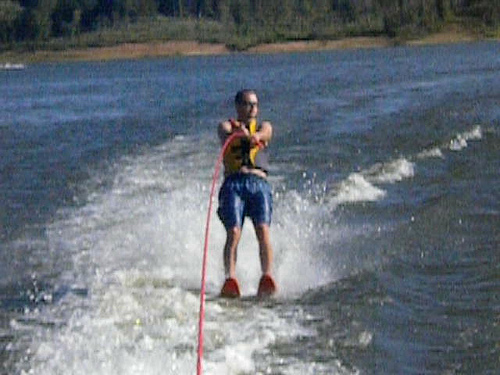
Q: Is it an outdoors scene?
A: Yes, it is outdoors.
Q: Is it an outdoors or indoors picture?
A: It is outdoors.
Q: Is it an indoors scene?
A: No, it is outdoors.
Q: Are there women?
A: No, there are no women.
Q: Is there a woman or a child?
A: No, there are no women or children.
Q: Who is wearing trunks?
A: The man is wearing trunks.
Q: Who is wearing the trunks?
A: The man is wearing trunks.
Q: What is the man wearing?
A: The man is wearing trunks.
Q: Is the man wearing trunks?
A: Yes, the man is wearing trunks.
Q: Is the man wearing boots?
A: No, the man is wearing trunks.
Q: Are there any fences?
A: No, there are no fences.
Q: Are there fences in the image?
A: No, there are no fences.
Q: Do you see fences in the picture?
A: No, there are no fences.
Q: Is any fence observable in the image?
A: No, there are no fences.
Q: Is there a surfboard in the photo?
A: No, there are no surfboards.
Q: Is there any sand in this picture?
A: Yes, there is sand.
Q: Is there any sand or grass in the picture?
A: Yes, there is sand.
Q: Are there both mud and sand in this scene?
A: No, there is sand but no mud.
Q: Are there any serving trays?
A: No, there are no serving trays.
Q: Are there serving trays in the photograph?
A: No, there are no serving trays.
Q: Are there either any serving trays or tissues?
A: No, there are no serving trays or tissues.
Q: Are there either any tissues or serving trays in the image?
A: No, there are no serving trays or tissues.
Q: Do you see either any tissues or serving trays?
A: No, there are no serving trays or tissues.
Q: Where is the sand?
A: The sand is on the beach.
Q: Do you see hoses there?
A: No, there are no hoses.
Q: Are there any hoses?
A: No, there are no hoses.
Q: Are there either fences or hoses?
A: No, there are no hoses or fences.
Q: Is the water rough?
A: Yes, the water is rough.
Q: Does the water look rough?
A: Yes, the water is rough.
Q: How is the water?
A: The water is rough.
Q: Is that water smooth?
A: No, the water is rough.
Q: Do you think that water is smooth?
A: No, the water is rough.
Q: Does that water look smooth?
A: No, the water is rough.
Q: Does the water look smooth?
A: No, the water is rough.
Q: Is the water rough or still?
A: The water is rough.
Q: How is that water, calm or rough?
A: The water is rough.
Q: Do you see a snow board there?
A: No, there are no snowboards.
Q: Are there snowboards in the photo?
A: No, there are no snowboards.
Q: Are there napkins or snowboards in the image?
A: No, there are no snowboards or napkins.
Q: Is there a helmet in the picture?
A: No, there are no helmets.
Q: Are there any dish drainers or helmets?
A: No, there are no helmets or dish drainers.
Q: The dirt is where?
A: The dirt is on the shore.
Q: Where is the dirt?
A: The dirt is on the shore.